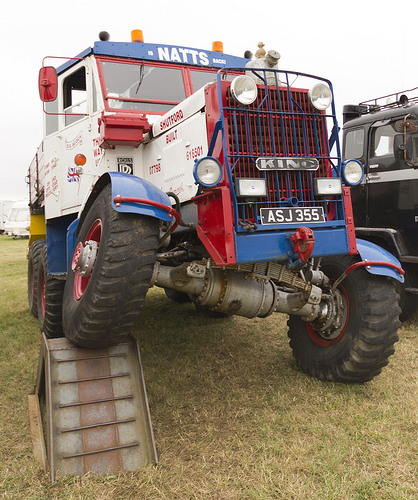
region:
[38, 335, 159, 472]
a silver jack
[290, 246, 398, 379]
a black tire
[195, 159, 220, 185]
a headlight on the truck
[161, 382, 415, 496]
grass under the truck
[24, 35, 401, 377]
a white and blue truck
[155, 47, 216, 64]
writing on the truck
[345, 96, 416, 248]
a black car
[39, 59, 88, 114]
a side mirror on the truck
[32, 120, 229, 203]
writing on the side of the car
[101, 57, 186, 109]
a windshield on a truck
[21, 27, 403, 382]
Large truck has black tire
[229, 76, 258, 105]
Round headlight on truck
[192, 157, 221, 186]
Round headlight on truck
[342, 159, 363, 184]
Round headlight on truck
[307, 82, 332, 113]
Round headlight on truck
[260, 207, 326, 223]
Black and white license plate on truck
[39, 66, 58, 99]
Red mirror on truck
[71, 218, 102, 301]
Red wheel on black tire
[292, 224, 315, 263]
Red clamp on truck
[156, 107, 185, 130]
Red sticker on truck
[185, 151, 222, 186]
headlight on the vehicle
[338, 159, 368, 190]
headlight on the vehicle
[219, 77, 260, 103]
headlight on the vehicle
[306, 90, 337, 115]
headlight on the vehicle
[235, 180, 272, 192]
headlight on the vehicle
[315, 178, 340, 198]
headlight on the vehicle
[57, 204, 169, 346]
tire on the vehicle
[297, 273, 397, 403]
tire on the vehicle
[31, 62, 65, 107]
mirror on the truck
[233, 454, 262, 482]
patch of dry grass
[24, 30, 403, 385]
a large white truck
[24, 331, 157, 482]
a metal ramp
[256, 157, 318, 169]
a black sign with the word KING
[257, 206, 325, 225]
a tag with the letters "ASJ355"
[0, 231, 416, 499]
green and brown grass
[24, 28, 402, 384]
a truck with two orange lights on top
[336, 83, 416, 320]
a black truck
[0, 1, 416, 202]
a white colored sky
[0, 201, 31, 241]
two white camper trailers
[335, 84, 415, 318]
a black truck with a silver horn on top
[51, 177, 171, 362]
a black big tire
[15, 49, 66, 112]
the side mirror is red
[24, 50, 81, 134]
the side mirror is red